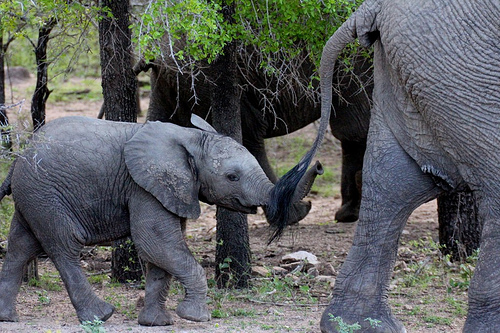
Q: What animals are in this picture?
A: Elephants.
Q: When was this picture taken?
A: Daytime.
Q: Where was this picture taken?
A: In the wild.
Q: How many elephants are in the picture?
A: 3.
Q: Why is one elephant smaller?
A: It's a baby.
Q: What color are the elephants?
A: Grey.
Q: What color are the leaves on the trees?
A: Green.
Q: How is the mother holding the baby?
A: With her tail.